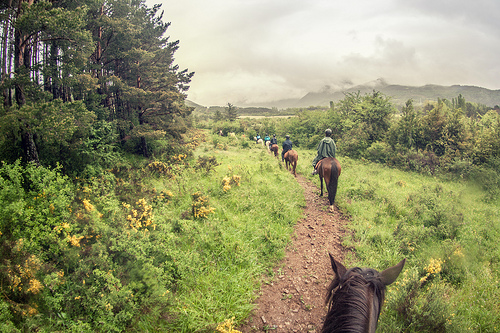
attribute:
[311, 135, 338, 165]
robe — green colored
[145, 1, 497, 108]
sky — hazy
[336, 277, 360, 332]
mane — colored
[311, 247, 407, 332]
horse — dark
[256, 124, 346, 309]
path — dirt